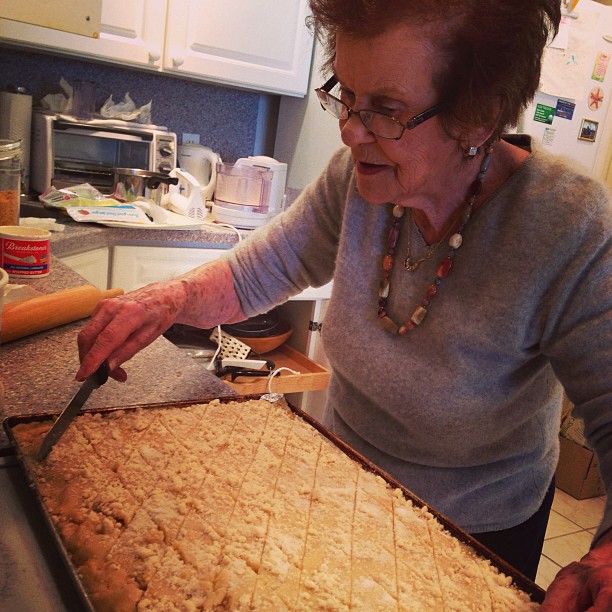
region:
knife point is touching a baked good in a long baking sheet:
[1, 358, 606, 606]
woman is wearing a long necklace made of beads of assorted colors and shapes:
[71, 0, 604, 605]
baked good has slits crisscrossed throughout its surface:
[0, 386, 539, 605]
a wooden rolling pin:
[0, 283, 124, 344]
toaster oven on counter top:
[22, 113, 253, 253]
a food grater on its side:
[207, 325, 260, 360]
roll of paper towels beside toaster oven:
[1, 85, 177, 198]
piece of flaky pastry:
[194, 467, 236, 535]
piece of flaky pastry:
[213, 495, 269, 571]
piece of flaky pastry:
[232, 467, 273, 522]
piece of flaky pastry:
[256, 489, 306, 564]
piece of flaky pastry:
[271, 468, 310, 526]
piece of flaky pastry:
[302, 496, 353, 562]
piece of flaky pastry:
[345, 522, 397, 600]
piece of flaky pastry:
[347, 481, 395, 563]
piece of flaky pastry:
[162, 439, 208, 500]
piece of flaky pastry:
[141, 417, 175, 472]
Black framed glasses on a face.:
[316, 71, 464, 142]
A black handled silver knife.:
[37, 355, 109, 463]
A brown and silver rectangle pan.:
[3, 391, 547, 609]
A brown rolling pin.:
[0, 284, 125, 343]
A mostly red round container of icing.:
[0, 225, 53, 280]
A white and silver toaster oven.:
[28, 104, 176, 195]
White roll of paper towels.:
[3, 90, 33, 195]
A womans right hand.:
[76, 288, 173, 384]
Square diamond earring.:
[467, 144, 477, 157]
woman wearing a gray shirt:
[71, 0, 609, 611]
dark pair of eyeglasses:
[314, 67, 486, 146]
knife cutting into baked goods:
[32, 362, 106, 467]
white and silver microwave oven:
[27, 107, 180, 204]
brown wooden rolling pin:
[0, 283, 125, 348]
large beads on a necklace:
[372, 115, 494, 337]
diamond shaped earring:
[465, 143, 478, 160]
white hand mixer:
[158, 165, 245, 244]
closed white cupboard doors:
[0, 2, 316, 99]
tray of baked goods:
[2, 391, 555, 611]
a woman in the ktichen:
[274, 43, 503, 354]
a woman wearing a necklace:
[351, 170, 536, 357]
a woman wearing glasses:
[319, 85, 444, 170]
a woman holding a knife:
[29, 226, 195, 465]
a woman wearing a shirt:
[216, 179, 525, 464]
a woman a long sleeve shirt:
[316, 170, 522, 409]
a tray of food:
[36, 328, 335, 611]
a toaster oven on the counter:
[22, 74, 161, 212]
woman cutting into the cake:
[37, 330, 131, 470]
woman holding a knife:
[34, 352, 129, 456]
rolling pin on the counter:
[4, 275, 140, 347]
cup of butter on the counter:
[6, 207, 55, 277]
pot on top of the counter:
[111, 157, 180, 214]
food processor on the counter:
[214, 146, 285, 224]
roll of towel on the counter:
[7, 85, 35, 185]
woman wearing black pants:
[445, 463, 570, 586]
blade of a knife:
[25, 325, 125, 467]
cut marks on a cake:
[13, 394, 500, 610]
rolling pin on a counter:
[2, 272, 128, 342]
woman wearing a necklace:
[346, 172, 495, 357]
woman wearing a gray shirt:
[195, 111, 608, 520]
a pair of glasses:
[304, 65, 454, 161]